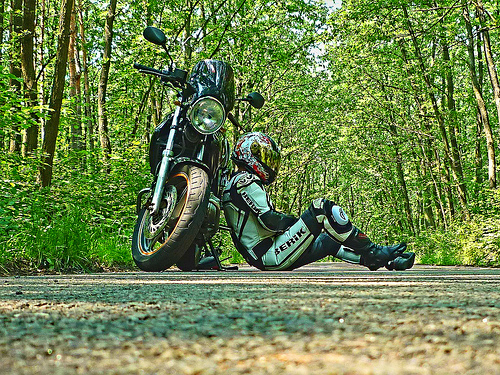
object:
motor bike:
[132, 26, 264, 272]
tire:
[131, 158, 211, 272]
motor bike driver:
[223, 132, 415, 270]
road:
[3, 261, 498, 373]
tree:
[36, 0, 74, 227]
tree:
[95, 0, 120, 178]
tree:
[431, 0, 470, 222]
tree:
[461, 0, 496, 188]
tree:
[21, 0, 40, 153]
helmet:
[231, 132, 280, 185]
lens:
[250, 140, 281, 175]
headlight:
[185, 94, 226, 137]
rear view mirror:
[143, 27, 173, 73]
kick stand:
[205, 233, 239, 271]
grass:
[0, 193, 137, 275]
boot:
[341, 225, 407, 270]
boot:
[360, 252, 417, 271]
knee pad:
[325, 200, 353, 234]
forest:
[3, 1, 499, 270]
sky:
[3, 2, 484, 180]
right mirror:
[233, 90, 266, 109]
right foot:
[364, 242, 406, 271]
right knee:
[309, 198, 343, 228]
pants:
[258, 198, 374, 272]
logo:
[271, 226, 306, 255]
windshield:
[187, 59, 236, 112]